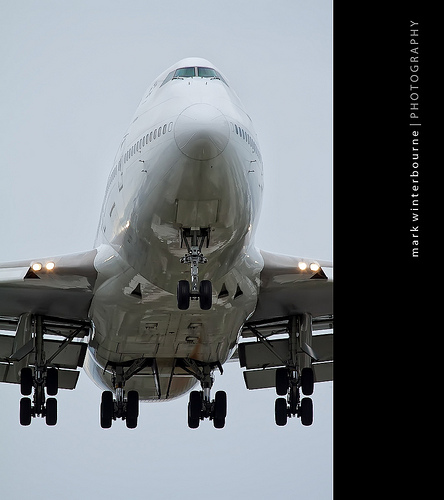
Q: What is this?
A: Plane.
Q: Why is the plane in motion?
A: Flying.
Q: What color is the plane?
A: White.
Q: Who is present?
A: No one.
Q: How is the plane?
A: Flying.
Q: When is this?
A: Daytime.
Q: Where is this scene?
A: In mid-air.